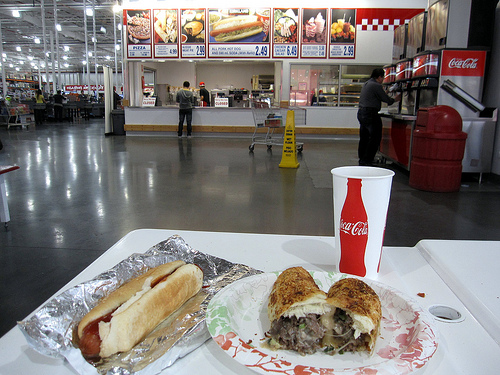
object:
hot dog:
[76, 260, 205, 362]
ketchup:
[92, 276, 170, 333]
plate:
[203, 269, 440, 375]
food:
[320, 277, 382, 355]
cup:
[328, 164, 393, 282]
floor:
[0, 120, 499, 336]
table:
[2, 225, 499, 372]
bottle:
[338, 178, 368, 279]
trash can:
[406, 103, 466, 193]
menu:
[122, 5, 357, 60]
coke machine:
[375, 49, 499, 174]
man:
[355, 69, 402, 167]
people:
[196, 81, 208, 109]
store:
[0, 0, 499, 374]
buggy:
[244, 88, 308, 157]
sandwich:
[266, 263, 329, 357]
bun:
[76, 258, 190, 342]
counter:
[126, 103, 356, 113]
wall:
[118, 0, 427, 135]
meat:
[275, 316, 318, 351]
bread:
[263, 262, 327, 349]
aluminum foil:
[16, 234, 264, 374]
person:
[175, 82, 197, 140]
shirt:
[172, 88, 199, 111]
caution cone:
[277, 111, 300, 169]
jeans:
[176, 110, 194, 135]